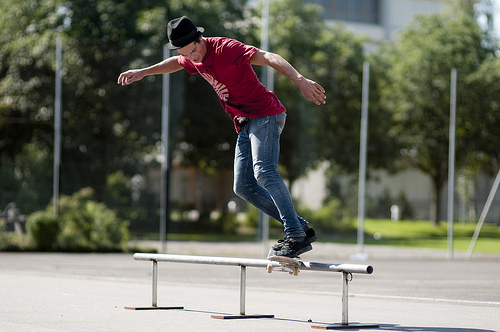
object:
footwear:
[272, 228, 317, 259]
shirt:
[177, 37, 287, 135]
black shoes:
[272, 227, 318, 258]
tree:
[0, 0, 500, 233]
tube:
[132, 252, 372, 274]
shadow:
[325, 322, 497, 332]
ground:
[0, 201, 488, 329]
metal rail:
[123, 252, 373, 329]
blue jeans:
[232, 110, 310, 238]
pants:
[233, 112, 309, 238]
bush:
[25, 185, 130, 253]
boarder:
[108, 9, 328, 268]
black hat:
[165, 16, 205, 51]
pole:
[341, 271, 349, 325]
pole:
[239, 265, 246, 314]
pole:
[151, 260, 158, 306]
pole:
[463, 168, 500, 260]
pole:
[446, 67, 457, 259]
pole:
[257, 3, 275, 253]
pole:
[159, 46, 171, 254]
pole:
[52, 34, 62, 215]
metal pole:
[355, 61, 368, 257]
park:
[0, 0, 500, 332]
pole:
[133, 252, 374, 274]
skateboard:
[265, 248, 302, 277]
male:
[117, 16, 326, 259]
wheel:
[266, 264, 273, 273]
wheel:
[292, 267, 298, 277]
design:
[201, 66, 234, 102]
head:
[177, 35, 207, 64]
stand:
[342, 271, 354, 325]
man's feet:
[277, 234, 313, 258]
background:
[0, 0, 500, 246]